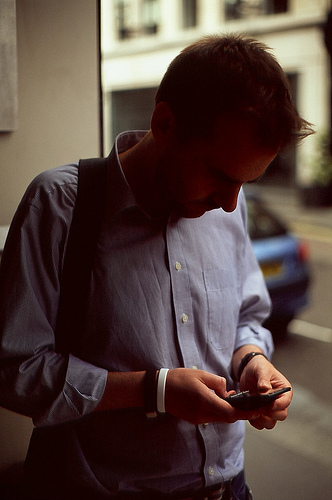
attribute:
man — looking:
[3, 24, 319, 499]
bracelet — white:
[154, 365, 170, 415]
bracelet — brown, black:
[143, 364, 156, 420]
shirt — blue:
[42, 190, 256, 386]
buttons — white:
[168, 248, 205, 369]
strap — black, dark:
[65, 156, 100, 361]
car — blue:
[239, 200, 312, 337]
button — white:
[168, 258, 191, 281]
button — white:
[174, 302, 195, 325]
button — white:
[184, 354, 203, 373]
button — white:
[198, 416, 215, 434]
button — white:
[203, 464, 219, 482]